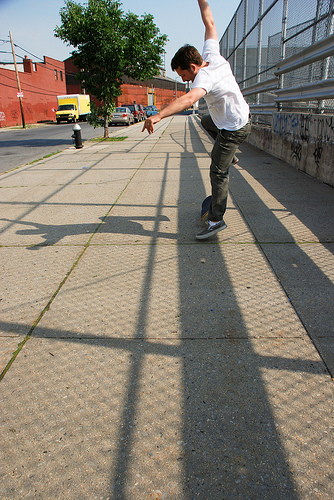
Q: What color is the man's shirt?
A: White.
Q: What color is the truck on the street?
A: Yellow.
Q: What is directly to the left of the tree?
A: A fire hydrant.